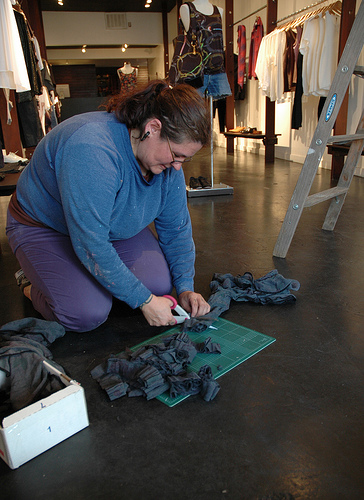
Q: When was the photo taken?
A: Day time.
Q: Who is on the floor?
A: A woman.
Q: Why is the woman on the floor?
A: Cutting fabric.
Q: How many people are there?
A: One.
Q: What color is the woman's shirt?
A: Blue.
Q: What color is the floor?
A: Black.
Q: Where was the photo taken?
A: At a store.